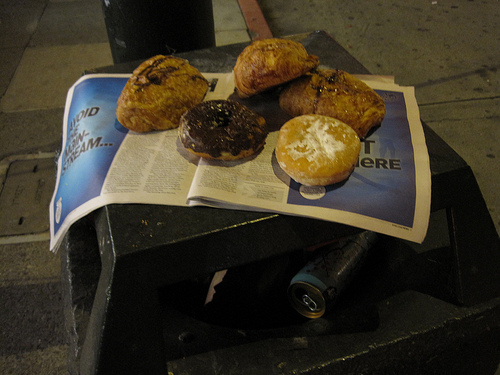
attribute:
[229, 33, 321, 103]
donut — brown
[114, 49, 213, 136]
donut — brown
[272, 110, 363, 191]
donut — powdered, circular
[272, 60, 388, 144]
donut — brown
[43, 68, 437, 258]
newspaper — grey, blue, open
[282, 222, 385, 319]
can — empty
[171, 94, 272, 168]
donut — circular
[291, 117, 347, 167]
powder — white, sugar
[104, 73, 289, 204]
area — white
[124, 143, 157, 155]
letters — small, black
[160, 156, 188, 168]
letters — printed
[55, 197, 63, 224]
design label — white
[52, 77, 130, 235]
left side — blue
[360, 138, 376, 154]
t — big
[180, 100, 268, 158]
chocolate — frosting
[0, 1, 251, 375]
sidewalk — grey, concrete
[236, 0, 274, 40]
stripe — red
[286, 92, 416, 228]
ad — blue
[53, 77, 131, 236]
ad — blue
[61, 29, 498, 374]
trash can — metal, black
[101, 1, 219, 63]
pole — light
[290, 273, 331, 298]
ring — blue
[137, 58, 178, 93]
drizzle — chocolate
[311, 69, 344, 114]
drizzle — chocolate